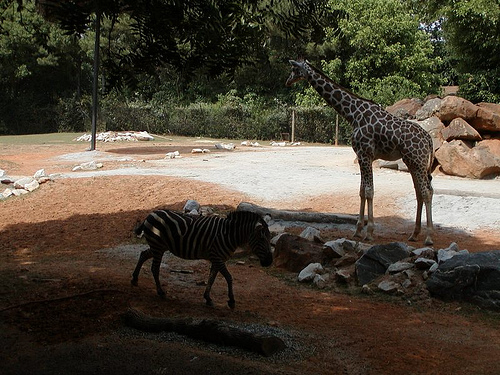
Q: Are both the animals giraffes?
A: No, they are giraffes and zebras.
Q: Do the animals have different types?
A: Yes, they are giraffes and zebras.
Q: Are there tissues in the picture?
A: No, there are no tissues.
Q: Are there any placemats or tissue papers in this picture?
A: No, there are no tissue papers or placemats.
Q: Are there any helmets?
A: No, there are no helmets.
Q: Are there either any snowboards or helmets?
A: No, there are no helmets or snowboards.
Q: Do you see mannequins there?
A: No, there are no mannequins.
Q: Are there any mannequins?
A: No, there are no mannequins.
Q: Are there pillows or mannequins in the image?
A: No, there are no mannequins or pillows.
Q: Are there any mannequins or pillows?
A: No, there are no mannequins or pillows.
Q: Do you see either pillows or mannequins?
A: No, there are no mannequins or pillows.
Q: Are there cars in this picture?
A: No, there are no cars.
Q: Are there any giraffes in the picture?
A: Yes, there is a giraffe.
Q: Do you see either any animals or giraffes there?
A: Yes, there is a giraffe.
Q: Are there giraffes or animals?
A: Yes, there is a giraffe.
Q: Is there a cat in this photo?
A: No, there are no cats.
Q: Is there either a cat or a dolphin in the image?
A: No, there are no cats or dolphins.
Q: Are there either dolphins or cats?
A: No, there are no cats or dolphins.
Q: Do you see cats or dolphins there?
A: No, there are no cats or dolphins.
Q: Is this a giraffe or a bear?
A: This is a giraffe.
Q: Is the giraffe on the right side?
A: Yes, the giraffe is on the right of the image.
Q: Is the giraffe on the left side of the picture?
A: No, the giraffe is on the right of the image.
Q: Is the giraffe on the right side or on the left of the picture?
A: The giraffe is on the right of the image.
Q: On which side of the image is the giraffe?
A: The giraffe is on the right of the image.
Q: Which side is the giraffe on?
A: The giraffe is on the right of the image.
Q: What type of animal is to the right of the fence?
A: The animal is a giraffe.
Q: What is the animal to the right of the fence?
A: The animal is a giraffe.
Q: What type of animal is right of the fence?
A: The animal is a giraffe.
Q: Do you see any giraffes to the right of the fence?
A: Yes, there is a giraffe to the right of the fence.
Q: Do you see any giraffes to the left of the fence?
A: No, the giraffe is to the right of the fence.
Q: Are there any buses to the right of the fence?
A: No, there is a giraffe to the right of the fence.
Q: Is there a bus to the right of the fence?
A: No, there is a giraffe to the right of the fence.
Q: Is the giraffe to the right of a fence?
A: Yes, the giraffe is to the right of a fence.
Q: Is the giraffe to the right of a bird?
A: No, the giraffe is to the right of a fence.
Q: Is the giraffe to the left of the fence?
A: No, the giraffe is to the right of the fence.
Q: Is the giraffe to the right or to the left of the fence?
A: The giraffe is to the right of the fence.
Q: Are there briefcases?
A: No, there are no briefcases.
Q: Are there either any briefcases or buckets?
A: No, there are no briefcases or buckets.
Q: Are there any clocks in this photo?
A: No, there are no clocks.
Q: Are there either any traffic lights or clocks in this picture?
A: No, there are no clocks or traffic lights.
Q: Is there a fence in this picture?
A: Yes, there is a fence.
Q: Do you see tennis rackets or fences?
A: Yes, there is a fence.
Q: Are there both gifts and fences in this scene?
A: No, there is a fence but no gifts.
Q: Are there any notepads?
A: No, there are no notepads.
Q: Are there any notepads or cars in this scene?
A: No, there are no notepads or cars.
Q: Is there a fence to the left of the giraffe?
A: Yes, there is a fence to the left of the giraffe.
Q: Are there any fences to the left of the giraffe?
A: Yes, there is a fence to the left of the giraffe.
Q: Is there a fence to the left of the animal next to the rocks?
A: Yes, there is a fence to the left of the giraffe.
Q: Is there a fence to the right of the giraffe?
A: No, the fence is to the left of the giraffe.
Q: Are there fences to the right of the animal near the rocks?
A: No, the fence is to the left of the giraffe.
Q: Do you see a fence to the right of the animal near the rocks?
A: No, the fence is to the left of the giraffe.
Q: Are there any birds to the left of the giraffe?
A: No, there is a fence to the left of the giraffe.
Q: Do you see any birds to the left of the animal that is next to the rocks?
A: No, there is a fence to the left of the giraffe.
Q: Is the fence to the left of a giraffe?
A: Yes, the fence is to the left of a giraffe.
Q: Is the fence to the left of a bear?
A: No, the fence is to the left of a giraffe.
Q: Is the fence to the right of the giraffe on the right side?
A: No, the fence is to the left of the giraffe.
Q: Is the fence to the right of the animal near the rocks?
A: No, the fence is to the left of the giraffe.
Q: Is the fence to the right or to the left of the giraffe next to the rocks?
A: The fence is to the left of the giraffe.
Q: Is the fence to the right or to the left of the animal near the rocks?
A: The fence is to the left of the giraffe.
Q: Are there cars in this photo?
A: No, there are no cars.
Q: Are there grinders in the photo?
A: No, there are no grinders.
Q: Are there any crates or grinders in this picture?
A: No, there are no grinders or crates.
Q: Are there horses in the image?
A: No, there are no horses.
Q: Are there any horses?
A: No, there are no horses.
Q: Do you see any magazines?
A: No, there are no magazines.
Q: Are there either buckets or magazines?
A: No, there are no magazines or buckets.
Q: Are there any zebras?
A: Yes, there is a zebra.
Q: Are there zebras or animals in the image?
A: Yes, there is a zebra.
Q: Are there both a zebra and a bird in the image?
A: No, there is a zebra but no birds.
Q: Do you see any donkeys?
A: No, there are no donkeys.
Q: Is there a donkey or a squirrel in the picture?
A: No, there are no donkeys or squirrels.